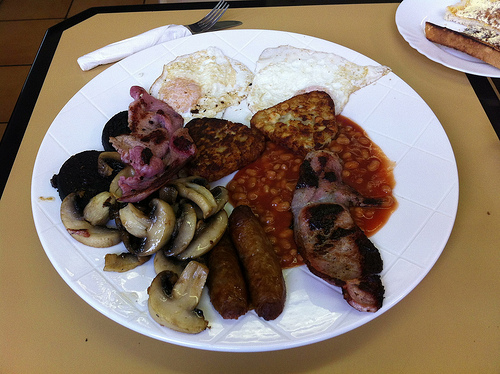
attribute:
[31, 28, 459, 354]
plate — white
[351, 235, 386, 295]
char — black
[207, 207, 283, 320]
sausages — cooked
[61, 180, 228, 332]
mushrooms — brown, cooked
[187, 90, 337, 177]
hash browns — brown, cooked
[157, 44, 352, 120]
eggs — cooked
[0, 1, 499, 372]
table — tan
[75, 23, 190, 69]
napkin — white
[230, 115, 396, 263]
beans — baked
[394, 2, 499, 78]
plate — white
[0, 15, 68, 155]
edges — black